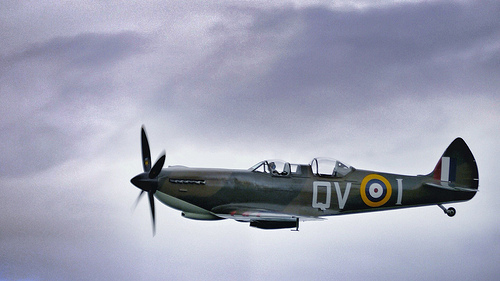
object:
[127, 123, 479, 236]
plane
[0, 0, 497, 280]
sky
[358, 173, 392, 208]
bullseye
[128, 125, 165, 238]
propeller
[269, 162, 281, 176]
pilot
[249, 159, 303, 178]
cockpit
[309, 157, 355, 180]
cockpit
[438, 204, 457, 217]
landing gear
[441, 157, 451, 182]
stripes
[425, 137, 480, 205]
tail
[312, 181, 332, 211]
q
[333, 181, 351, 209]
v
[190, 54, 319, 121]
clouds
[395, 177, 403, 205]
i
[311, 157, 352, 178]
cover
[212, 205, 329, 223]
wing